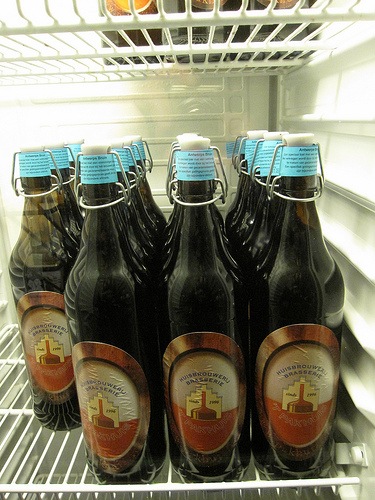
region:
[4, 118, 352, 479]
bottles standing together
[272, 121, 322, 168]
the top of the bottle is white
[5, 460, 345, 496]
the shelf is white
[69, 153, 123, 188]
the label is blue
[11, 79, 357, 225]
the inside of the refrigerator is white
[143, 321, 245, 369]
the edge of the label is brown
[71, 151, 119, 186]
the letters are black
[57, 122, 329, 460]
many bottles in a row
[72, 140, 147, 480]
a brown bottle of beer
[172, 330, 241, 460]
a lable on a beer bottle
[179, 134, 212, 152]
a cork in the bottle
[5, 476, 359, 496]
a white wire rack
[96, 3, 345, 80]
a white rack above the bottles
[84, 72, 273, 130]
a white wall with a reflection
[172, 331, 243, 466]
a gold tan and brown label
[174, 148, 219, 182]
a blue label on a bottle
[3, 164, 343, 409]
beer in the fridge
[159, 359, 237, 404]
writing on the beer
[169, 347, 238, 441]
logo on the beer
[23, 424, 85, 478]
rack under the beer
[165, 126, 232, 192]
top of the bottle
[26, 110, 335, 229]
tops of the beer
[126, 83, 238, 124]
white background of photo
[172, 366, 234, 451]
light and dark logo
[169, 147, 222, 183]
blue sticker on beer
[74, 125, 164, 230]
row of beer in photo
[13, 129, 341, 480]
Refrigerator shelf full of beer bottles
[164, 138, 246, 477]
Beer bottle with white lid and blue paper seal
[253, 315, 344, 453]
Copper and red beer label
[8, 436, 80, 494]
Refrigerator shelf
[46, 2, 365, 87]
Bottom of refrigerator shelf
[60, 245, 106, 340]
Reflection of refrigerator interior on beer bottle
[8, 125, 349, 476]
Neatly ordered beer bottles on refrigerator shelf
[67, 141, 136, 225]
Wire attached beer bottle cap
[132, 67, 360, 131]
White interior refrigerator wall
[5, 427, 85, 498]
White plastic coated wire refrigerator shelf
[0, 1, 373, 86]
the top wired white shelf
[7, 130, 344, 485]
the group of bottles on the shelf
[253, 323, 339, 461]
the label on the bottle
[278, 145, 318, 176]
the blue label on the bottle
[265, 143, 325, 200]
the metal piece on the bottle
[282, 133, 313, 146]
the white piece on the top of the bottle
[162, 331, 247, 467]
the label on the bottle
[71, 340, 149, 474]
the label on the bottle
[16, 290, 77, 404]
the label on the bottle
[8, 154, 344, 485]
the light reflecting on the bottles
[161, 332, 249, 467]
A label on a bottle